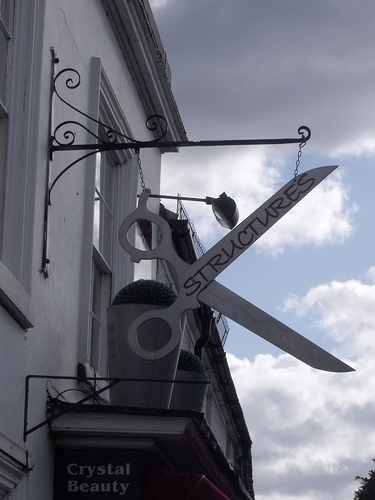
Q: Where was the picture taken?
A: Storefront.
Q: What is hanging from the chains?
A: Scissors.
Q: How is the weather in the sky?
A: Cloudy.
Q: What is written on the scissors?
A: STRUCTURES.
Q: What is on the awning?
A: Plants in pots.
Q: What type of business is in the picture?
A: Hair salon.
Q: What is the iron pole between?
A: Windows.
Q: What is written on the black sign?
A: Crystal Beauty.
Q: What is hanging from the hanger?
A: Giant scissors.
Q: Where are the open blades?
A: Above salon.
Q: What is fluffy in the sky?
A: Clouds.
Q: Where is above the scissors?
A: Light.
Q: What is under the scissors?
A: Metal sign holder.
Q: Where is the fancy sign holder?
A: Along building.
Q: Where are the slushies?
A: On ledge.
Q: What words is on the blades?
A: Structures.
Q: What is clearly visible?
A: Scissors.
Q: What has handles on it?
A: Scissors.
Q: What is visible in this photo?
A: Scissors.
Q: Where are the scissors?
A: Visible hanging above shop.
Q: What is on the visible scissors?
A: Red lettering.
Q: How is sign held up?
A: By a black iron bar.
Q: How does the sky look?
A: Blue with clouds.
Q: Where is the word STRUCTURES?
A: On a sign that looks like scissors.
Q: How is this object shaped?
A: Like a pair of scissors.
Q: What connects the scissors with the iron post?
A: Metal chains.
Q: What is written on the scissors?
A: Structures.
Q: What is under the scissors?
A: Green plants in silver tins.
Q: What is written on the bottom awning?
A: Crystal Beauty.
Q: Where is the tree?
A: Lower right corner.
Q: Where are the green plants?
A: In silver tins.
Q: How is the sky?
A: Gray and partly cloudy.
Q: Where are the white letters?
A: On the brown awning.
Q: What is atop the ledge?
A: Potted plants.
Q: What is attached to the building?
A: Scissors.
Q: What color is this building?
A: White.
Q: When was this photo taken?
A: In the daytime.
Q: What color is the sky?
A: Blue.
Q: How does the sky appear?
A: Cloudy.